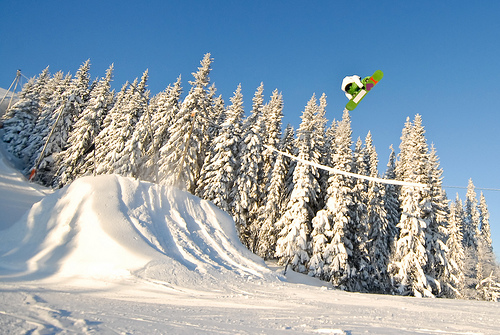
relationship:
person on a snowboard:
[340, 74, 367, 100] [344, 68, 385, 112]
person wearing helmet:
[340, 74, 367, 100] [346, 84, 361, 95]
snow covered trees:
[151, 160, 204, 184] [2, 51, 500, 306]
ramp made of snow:
[29, 177, 295, 295] [9, 288, 499, 334]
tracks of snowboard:
[122, 176, 469, 334] [344, 68, 385, 112]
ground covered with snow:
[1, 147, 493, 334] [9, 288, 499, 334]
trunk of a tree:
[281, 250, 297, 278] [275, 129, 312, 278]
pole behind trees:
[1, 68, 31, 116] [2, 51, 500, 306]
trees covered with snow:
[2, 51, 500, 306] [151, 160, 204, 184]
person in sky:
[340, 74, 367, 100] [0, 1, 499, 258]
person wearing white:
[340, 74, 367, 100] [340, 75, 365, 100]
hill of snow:
[2, 89, 295, 334] [9, 288, 499, 334]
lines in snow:
[10, 280, 119, 334] [9, 288, 499, 334]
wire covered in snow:
[261, 141, 500, 201] [151, 160, 204, 184]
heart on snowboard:
[363, 81, 376, 92] [344, 68, 385, 112]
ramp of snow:
[29, 177, 295, 295] [9, 288, 499, 334]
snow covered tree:
[151, 160, 204, 184] [155, 50, 217, 193]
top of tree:
[189, 49, 221, 77] [155, 50, 217, 193]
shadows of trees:
[1, 156, 87, 274] [2, 51, 500, 306]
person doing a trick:
[340, 74, 367, 100] [338, 67, 386, 115]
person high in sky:
[340, 74, 367, 100] [0, 1, 499, 258]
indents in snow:
[275, 318, 429, 335] [9, 288, 499, 334]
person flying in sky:
[340, 74, 367, 100] [0, 1, 499, 258]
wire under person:
[261, 141, 500, 201] [340, 74, 367, 100]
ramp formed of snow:
[29, 177, 295, 295] [9, 288, 499, 334]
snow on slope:
[9, 288, 499, 334] [1, 147, 493, 334]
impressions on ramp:
[111, 173, 274, 285] [29, 177, 295, 295]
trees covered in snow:
[2, 51, 500, 306] [151, 160, 204, 184]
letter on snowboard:
[369, 77, 380, 85] [344, 68, 385, 112]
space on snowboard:
[351, 88, 367, 105] [344, 68, 385, 112]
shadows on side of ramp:
[1, 156, 87, 274] [29, 177, 295, 295]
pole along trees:
[29, 102, 67, 182] [2, 51, 500, 306]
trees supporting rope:
[2, 51, 500, 306] [261, 141, 500, 201]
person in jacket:
[340, 74, 367, 100] [339, 74, 365, 100]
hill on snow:
[2, 89, 295, 334] [151, 160, 204, 184]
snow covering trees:
[151, 160, 204, 184] [2, 51, 500, 306]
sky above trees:
[0, 1, 499, 258] [2, 51, 500, 306]